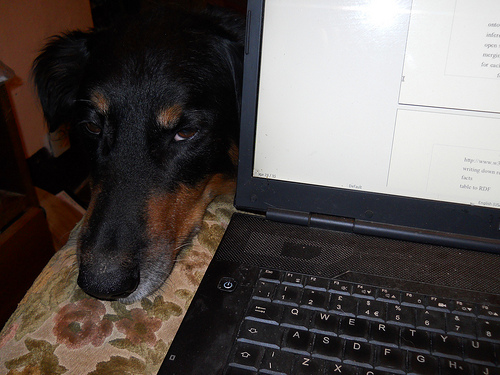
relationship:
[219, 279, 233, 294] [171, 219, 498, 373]
button on keyboard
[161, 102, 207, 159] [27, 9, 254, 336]
eye of dog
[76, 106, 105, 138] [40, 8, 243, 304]
eye of dog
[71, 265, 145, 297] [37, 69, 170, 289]
nose of dog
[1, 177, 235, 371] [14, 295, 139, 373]
chair has pattern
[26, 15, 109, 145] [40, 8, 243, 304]
ear of dog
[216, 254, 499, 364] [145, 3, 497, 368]
key board of laptop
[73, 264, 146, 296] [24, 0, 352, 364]
nose on dog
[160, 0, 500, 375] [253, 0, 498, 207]
laptop has screen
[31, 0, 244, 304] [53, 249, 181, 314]
dog has nose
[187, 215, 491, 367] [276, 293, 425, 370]
key board has keys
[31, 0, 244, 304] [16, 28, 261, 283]
dog has head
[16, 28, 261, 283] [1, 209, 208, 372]
head rests on chair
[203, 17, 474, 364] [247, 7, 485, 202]
laptop has screen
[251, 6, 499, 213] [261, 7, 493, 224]
light shining on screen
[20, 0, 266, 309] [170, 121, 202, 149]
dog has eye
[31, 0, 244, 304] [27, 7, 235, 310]
dog has head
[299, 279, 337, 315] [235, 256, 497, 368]
key on keyboard